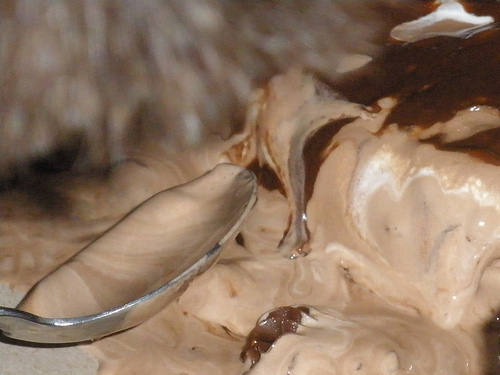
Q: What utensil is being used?
A: Spoon.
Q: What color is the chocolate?
A: Brown.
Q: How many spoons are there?
A: One.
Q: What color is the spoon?
A: Silver.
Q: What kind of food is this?
A: Ice cream.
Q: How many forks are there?
A: Zero.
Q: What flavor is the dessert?
A: Chocolate.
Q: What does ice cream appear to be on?
A: Cake.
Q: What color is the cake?
A: Dark brown.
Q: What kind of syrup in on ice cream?
A: Chocolate.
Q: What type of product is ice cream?
A: Dairy.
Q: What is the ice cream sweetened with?
A: Sugar.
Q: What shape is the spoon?
A: Oval.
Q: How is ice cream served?
A: Cold.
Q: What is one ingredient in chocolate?
A: Cocoa.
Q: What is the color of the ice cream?
A: Brown.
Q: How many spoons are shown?
A: One.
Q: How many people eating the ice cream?
A: Zero.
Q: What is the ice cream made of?
A: Chocolate and milk and cream.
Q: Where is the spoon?
A: On the ice cream.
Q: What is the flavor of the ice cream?
A: Chocolate.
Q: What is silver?
A: The spoon.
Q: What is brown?
A: The ice cream.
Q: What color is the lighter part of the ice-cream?
A: Light brown/beige.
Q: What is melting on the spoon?
A: Ice-cream.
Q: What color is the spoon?
A: Silver.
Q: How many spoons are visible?
A: One.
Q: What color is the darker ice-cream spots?
A: Dark brown.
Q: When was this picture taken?
A: While eating ice-cream.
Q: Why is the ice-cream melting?
A: It's not cold enough.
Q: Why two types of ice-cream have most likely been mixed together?
A: Chocolate and vanilla.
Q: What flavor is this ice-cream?
A: Chocolate.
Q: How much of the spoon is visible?
A: Just the circular part, not the handle.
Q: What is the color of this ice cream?
A: Cream and brown.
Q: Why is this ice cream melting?
A: Because of warm weather.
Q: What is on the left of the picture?
A: A spoon.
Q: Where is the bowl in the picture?
A: Not visible.